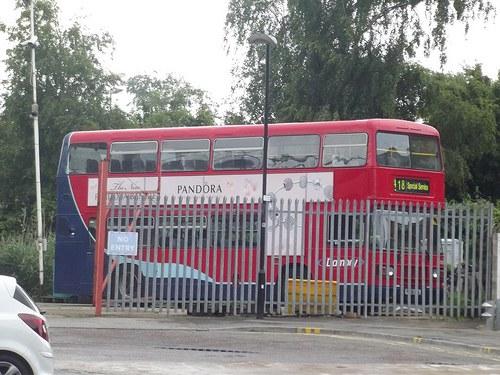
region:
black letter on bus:
[176, 183, 183, 193]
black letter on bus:
[179, 184, 188, 194]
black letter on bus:
[185, 182, 197, 196]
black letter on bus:
[195, 182, 204, 194]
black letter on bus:
[208, 182, 216, 195]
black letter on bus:
[215, 184, 225, 192]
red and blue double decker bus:
[42, 115, 454, 315]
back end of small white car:
[1, 268, 57, 373]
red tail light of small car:
[17, 308, 54, 348]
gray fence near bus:
[87, 155, 499, 331]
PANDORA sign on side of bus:
[170, 180, 225, 197]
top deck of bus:
[55, 111, 452, 209]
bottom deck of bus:
[45, 204, 452, 304]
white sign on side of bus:
[79, 172, 339, 209]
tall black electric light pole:
[237, 28, 287, 313]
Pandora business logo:
[173, 182, 225, 194]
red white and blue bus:
[51, 117, 445, 305]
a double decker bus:
[52, 116, 450, 308]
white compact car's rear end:
[0, 271, 54, 373]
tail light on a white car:
[18, 312, 50, 340]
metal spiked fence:
[102, 193, 496, 318]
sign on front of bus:
[390, 174, 432, 196]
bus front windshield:
[370, 207, 440, 253]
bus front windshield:
[374, 128, 445, 171]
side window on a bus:
[264, 138, 321, 169]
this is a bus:
[27, 97, 486, 309]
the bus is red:
[41, 80, 473, 325]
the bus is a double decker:
[29, 70, 474, 339]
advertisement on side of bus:
[111, 163, 331, 210]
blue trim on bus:
[39, 143, 116, 305]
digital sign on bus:
[383, 172, 442, 197]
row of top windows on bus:
[109, 135, 370, 168]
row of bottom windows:
[78, 195, 386, 260]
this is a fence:
[81, 163, 496, 337]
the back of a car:
[0, 259, 70, 371]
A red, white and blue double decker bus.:
[51, 120, 446, 308]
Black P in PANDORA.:
[175, 184, 181, 195]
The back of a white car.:
[0, 272, 55, 374]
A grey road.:
[46, 311, 495, 373]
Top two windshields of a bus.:
[372, 130, 441, 173]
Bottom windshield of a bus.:
[375, 207, 436, 256]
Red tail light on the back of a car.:
[19, 313, 51, 344]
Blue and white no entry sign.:
[105, 229, 140, 257]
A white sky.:
[0, 0, 497, 124]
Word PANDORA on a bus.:
[176, 184, 222, 195]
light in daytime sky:
[0, 0, 498, 124]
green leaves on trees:
[228, 1, 483, 129]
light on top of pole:
[240, 31, 278, 316]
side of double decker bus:
[51, 118, 445, 311]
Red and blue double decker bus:
[41, 108, 443, 323]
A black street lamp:
[237, 25, 288, 325]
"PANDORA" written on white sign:
[167, 175, 227, 196]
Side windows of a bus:
[60, 125, 376, 180]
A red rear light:
[7, 302, 52, 342]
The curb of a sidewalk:
[225, 320, 495, 360]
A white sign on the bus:
[80, 165, 340, 210]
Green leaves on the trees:
[0, 0, 496, 231]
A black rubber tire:
[0, 344, 38, 373]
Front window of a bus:
[366, 202, 446, 259]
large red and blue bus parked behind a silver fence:
[50, 115, 442, 308]